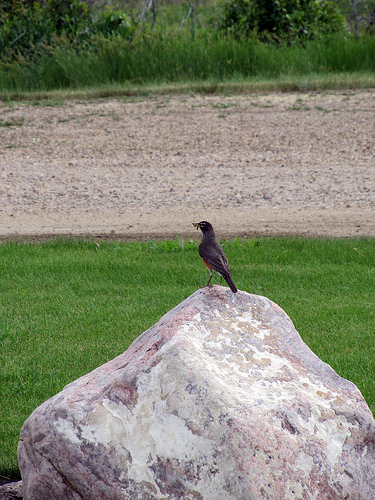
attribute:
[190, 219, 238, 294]
bird — black, dark, small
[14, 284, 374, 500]
rock — large, big, white, different shaped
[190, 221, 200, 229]
beak — black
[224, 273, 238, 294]
tail feather — long, black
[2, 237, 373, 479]
grass — green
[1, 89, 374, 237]
road — dirt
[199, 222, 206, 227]
eye — black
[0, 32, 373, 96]
grass — tall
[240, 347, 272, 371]
speck — brown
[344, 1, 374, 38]
tree — brown